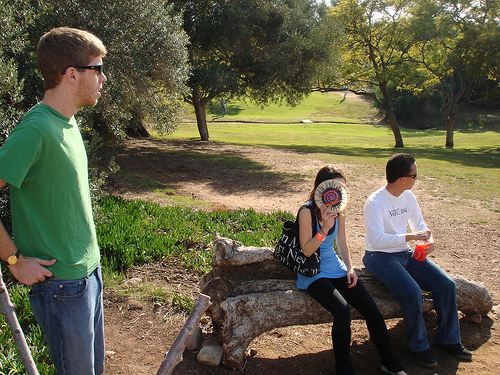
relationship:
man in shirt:
[5, 24, 119, 371] [2, 106, 107, 281]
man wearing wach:
[5, 24, 119, 371] [5, 252, 23, 268]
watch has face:
[5, 252, 23, 268] [9, 254, 19, 263]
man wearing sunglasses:
[5, 24, 119, 371] [74, 60, 105, 76]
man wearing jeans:
[5, 24, 119, 371] [27, 266, 111, 374]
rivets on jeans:
[54, 278, 86, 300] [27, 266, 111, 374]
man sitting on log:
[360, 147, 474, 364] [160, 218, 497, 369]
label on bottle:
[417, 251, 427, 258] [409, 236, 434, 264]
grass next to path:
[89, 78, 500, 305] [94, 129, 500, 374]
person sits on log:
[267, 165, 415, 371] [160, 218, 497, 369]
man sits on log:
[361, 152, 472, 369] [160, 218, 497, 369]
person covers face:
[293, 165, 409, 375] [330, 174, 350, 209]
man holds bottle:
[360, 147, 474, 364] [409, 236, 434, 264]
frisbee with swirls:
[314, 180, 351, 213] [321, 188, 343, 204]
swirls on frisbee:
[321, 188, 343, 204] [314, 180, 351, 213]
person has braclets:
[293, 165, 409, 375] [317, 233, 325, 246]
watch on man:
[0, 249, 22, 266] [5, 24, 119, 371]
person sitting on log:
[267, 165, 415, 371] [160, 218, 497, 369]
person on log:
[267, 165, 415, 371] [160, 218, 497, 369]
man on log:
[361, 152, 472, 369] [160, 218, 497, 369]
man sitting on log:
[361, 152, 472, 369] [160, 218, 497, 369]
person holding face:
[293, 165, 409, 375] [330, 174, 350, 209]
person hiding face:
[293, 165, 409, 375] [330, 174, 350, 209]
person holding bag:
[293, 165, 409, 375] [271, 204, 322, 277]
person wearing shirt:
[293, 165, 409, 375] [294, 205, 348, 291]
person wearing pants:
[293, 165, 409, 375] [312, 278, 403, 363]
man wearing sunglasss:
[5, 24, 119, 371] [71, 61, 109, 77]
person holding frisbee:
[293, 165, 409, 375] [314, 180, 351, 213]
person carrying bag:
[293, 165, 409, 375] [271, 204, 322, 277]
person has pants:
[293, 165, 409, 375] [312, 278, 403, 363]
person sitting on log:
[293, 165, 409, 375] [160, 218, 497, 369]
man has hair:
[5, 24, 119, 371] [34, 23, 106, 87]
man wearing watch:
[5, 24, 119, 371] [0, 249, 22, 266]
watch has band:
[5, 248, 25, 267] [6, 243, 23, 265]